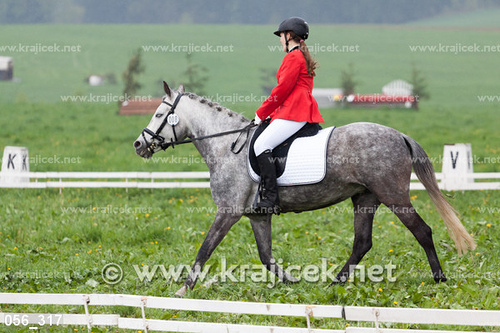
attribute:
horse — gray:
[133, 79, 479, 283]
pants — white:
[248, 110, 339, 169]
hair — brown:
[299, 34, 326, 70]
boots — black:
[236, 174, 261, 221]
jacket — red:
[243, 42, 355, 132]